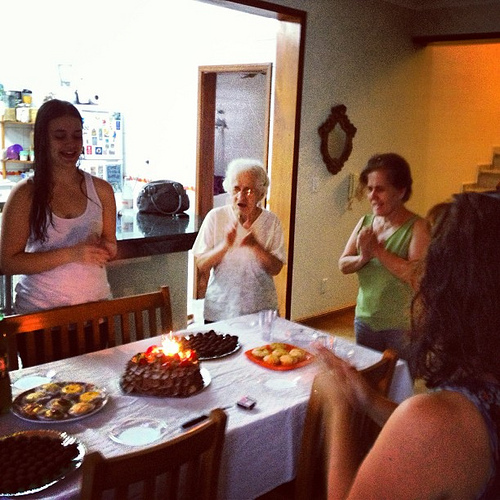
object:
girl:
[0, 99, 118, 374]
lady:
[191, 158, 287, 324]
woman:
[339, 152, 432, 345]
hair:
[405, 191, 500, 423]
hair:
[27, 99, 104, 247]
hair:
[358, 152, 413, 203]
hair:
[222, 157, 270, 202]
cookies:
[251, 347, 269, 356]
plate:
[244, 342, 315, 370]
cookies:
[215, 348, 223, 355]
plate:
[173, 330, 241, 360]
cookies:
[59, 442, 80, 462]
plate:
[0, 429, 87, 499]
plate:
[108, 416, 169, 448]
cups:
[259, 309, 278, 341]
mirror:
[327, 123, 347, 160]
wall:
[290, 0, 500, 321]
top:
[431, 387, 499, 499]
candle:
[168, 331, 173, 355]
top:
[13, 172, 115, 317]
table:
[0, 310, 416, 500]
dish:
[244, 341, 317, 371]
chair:
[0, 285, 172, 373]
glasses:
[232, 188, 255, 196]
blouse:
[191, 204, 287, 322]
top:
[354, 211, 422, 332]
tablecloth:
[0, 310, 416, 498]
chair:
[47, 407, 230, 499]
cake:
[120, 352, 205, 397]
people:
[0, 99, 118, 316]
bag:
[136, 180, 190, 214]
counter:
[110, 208, 208, 261]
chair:
[293, 348, 399, 499]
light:
[433, 41, 500, 91]